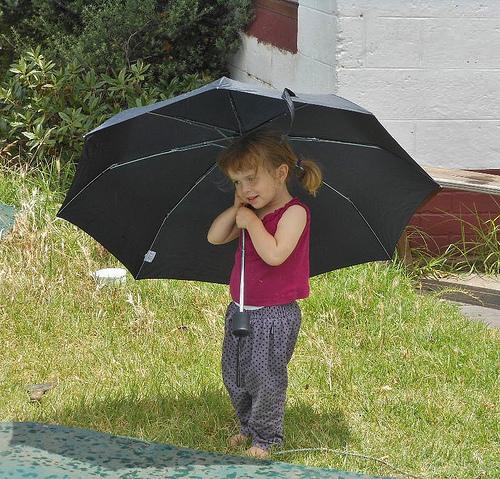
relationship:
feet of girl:
[224, 431, 271, 461] [190, 129, 315, 459]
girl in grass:
[213, 101, 363, 459] [8, 155, 497, 476]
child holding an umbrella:
[202, 122, 331, 461] [43, 74, 440, 290]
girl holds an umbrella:
[207, 125, 326, 463] [43, 74, 440, 290]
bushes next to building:
[0, 0, 225, 175] [253, 4, 498, 188]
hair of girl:
[215, 130, 350, 190] [202, 135, 340, 468]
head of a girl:
[226, 126, 329, 219] [202, 135, 340, 468]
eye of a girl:
[248, 172, 255, 182] [198, 124, 328, 464]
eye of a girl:
[232, 176, 238, 189] [198, 124, 328, 464]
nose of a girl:
[236, 180, 256, 197] [202, 135, 340, 468]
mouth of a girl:
[243, 189, 267, 208] [198, 124, 328, 464]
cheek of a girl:
[249, 173, 275, 200] [205, 125, 317, 415]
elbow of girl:
[263, 241, 285, 272] [212, 132, 332, 460]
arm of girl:
[238, 210, 298, 266] [202, 135, 340, 468]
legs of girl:
[217, 336, 296, 438] [198, 124, 328, 464]